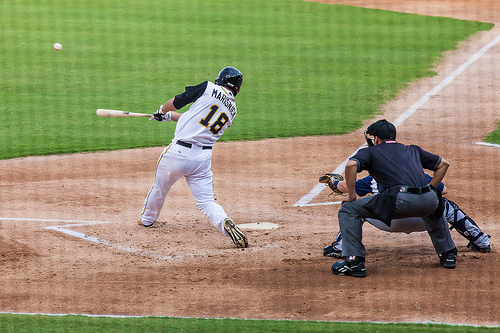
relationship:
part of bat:
[95, 107, 119, 117] [95, 108, 152, 117]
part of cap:
[364, 131, 373, 144] [368, 119, 397, 142]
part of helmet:
[216, 72, 238, 82] [213, 64, 246, 96]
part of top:
[207, 82, 236, 118] [170, 78, 238, 148]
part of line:
[295, 184, 341, 207] [295, 34, 499, 208]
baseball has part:
[53, 43, 64, 52] [57, 46, 61, 50]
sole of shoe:
[224, 219, 248, 248] [224, 218, 253, 249]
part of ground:
[301, 76, 340, 107] [0, 1, 496, 160]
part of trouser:
[205, 204, 227, 230] [142, 143, 231, 232]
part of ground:
[123, 18, 163, 46] [0, 1, 496, 160]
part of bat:
[146, 117, 152, 121] [95, 108, 152, 117]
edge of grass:
[0, 313, 499, 332] [2, 320, 495, 331]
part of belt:
[175, 140, 194, 150] [171, 137, 217, 150]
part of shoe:
[336, 268, 368, 278] [328, 262, 372, 277]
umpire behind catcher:
[334, 119, 460, 278] [319, 167, 494, 257]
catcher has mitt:
[319, 167, 494, 257] [318, 173, 349, 195]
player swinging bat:
[140, 66, 250, 248] [95, 108, 152, 117]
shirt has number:
[170, 78, 238, 148] [200, 106, 229, 135]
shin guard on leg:
[451, 201, 480, 224] [446, 200, 495, 253]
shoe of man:
[224, 218, 253, 249] [140, 66, 250, 248]